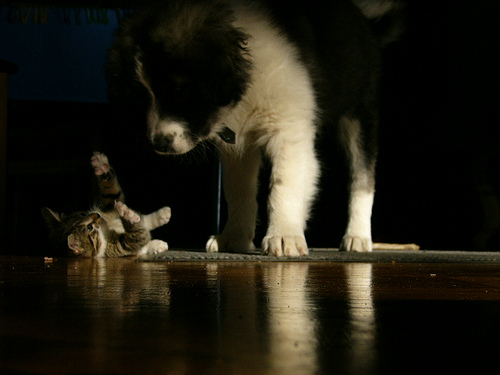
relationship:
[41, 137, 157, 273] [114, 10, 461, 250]
kitten under dog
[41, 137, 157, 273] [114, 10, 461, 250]
kitten below dog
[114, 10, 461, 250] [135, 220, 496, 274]
dog on rug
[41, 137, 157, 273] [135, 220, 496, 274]
kitten on rug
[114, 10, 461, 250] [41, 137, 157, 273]
dog near kitten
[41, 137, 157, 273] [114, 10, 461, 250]
kitten near dog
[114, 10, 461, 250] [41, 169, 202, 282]
dog looking at kitten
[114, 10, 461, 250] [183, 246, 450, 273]
dog standing on rug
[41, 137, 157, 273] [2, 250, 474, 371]
kitten laying on ground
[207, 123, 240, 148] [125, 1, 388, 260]
collar around dog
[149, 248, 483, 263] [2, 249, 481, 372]
rug on top of floor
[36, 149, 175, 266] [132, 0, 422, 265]
cat playing with dog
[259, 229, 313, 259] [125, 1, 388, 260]
paw of dog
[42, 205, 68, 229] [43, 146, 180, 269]
ear of kitten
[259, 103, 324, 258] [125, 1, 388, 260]
leg of dog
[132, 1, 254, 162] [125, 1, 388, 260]
head of dog